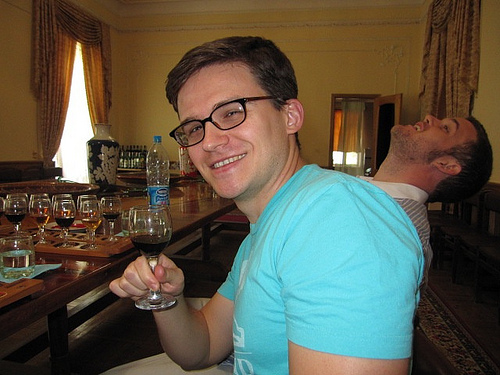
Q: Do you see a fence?
A: No, there are no fences.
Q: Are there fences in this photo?
A: No, there are no fences.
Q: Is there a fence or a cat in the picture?
A: No, there are no fences or cats.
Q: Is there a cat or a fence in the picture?
A: No, there are no fences or cats.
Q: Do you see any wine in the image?
A: Yes, there is wine.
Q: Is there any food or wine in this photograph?
A: Yes, there is wine.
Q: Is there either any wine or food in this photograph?
A: Yes, there is wine.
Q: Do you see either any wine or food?
A: Yes, there is wine.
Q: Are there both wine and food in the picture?
A: No, there is wine but no food.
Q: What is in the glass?
A: The wine is in the glass.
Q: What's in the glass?
A: The wine is in the glass.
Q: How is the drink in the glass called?
A: The drink is wine.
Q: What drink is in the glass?
A: The drink is wine.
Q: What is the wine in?
A: The wine is in the glass.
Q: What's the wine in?
A: The wine is in the glass.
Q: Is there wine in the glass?
A: Yes, there is wine in the glass.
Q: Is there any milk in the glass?
A: No, there is wine in the glass.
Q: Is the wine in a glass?
A: Yes, the wine is in a glass.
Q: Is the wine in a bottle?
A: No, the wine is in a glass.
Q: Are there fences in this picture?
A: No, there are no fences.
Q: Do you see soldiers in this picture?
A: No, there are no soldiers.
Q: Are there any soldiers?
A: No, there are no soldiers.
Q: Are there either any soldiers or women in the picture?
A: No, there are no soldiers or women.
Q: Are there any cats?
A: No, there are no cats.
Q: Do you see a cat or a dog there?
A: No, there are no cats or dogs.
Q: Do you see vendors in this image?
A: No, there are no vendors.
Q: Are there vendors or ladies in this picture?
A: No, there are no vendors or ladies.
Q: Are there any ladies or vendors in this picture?
A: No, there are no vendors or ladies.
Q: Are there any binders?
A: No, there are no binders.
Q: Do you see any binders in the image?
A: No, there are no binders.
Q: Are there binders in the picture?
A: No, there are no binders.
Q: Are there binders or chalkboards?
A: No, there are no binders or chalkboards.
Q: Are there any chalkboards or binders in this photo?
A: No, there are no binders or chalkboards.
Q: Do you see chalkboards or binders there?
A: No, there are no binders or chalkboards.